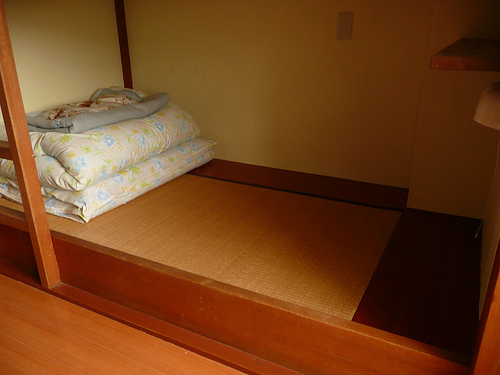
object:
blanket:
[20, 85, 171, 135]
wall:
[122, 0, 492, 166]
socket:
[337, 11, 353, 41]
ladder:
[1, 5, 62, 291]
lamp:
[474, 81, 500, 131]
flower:
[80, 99, 99, 108]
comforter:
[0, 85, 219, 223]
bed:
[0, 152, 499, 375]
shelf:
[428, 37, 500, 71]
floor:
[0, 331, 146, 374]